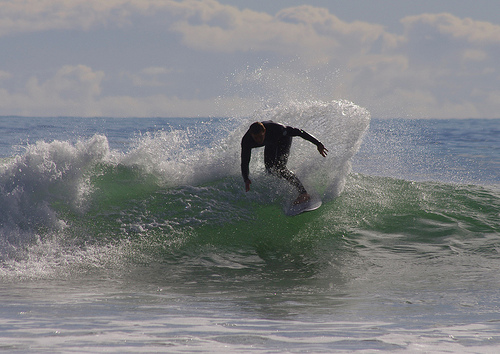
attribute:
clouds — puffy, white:
[1, 0, 498, 117]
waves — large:
[7, 128, 489, 293]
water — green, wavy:
[1, 94, 498, 351]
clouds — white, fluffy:
[17, 10, 467, 90]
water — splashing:
[88, 210, 238, 265]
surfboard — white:
[278, 187, 322, 218]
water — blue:
[311, 170, 483, 325]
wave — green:
[129, 186, 492, 236]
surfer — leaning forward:
[236, 120, 334, 210]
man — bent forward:
[241, 120, 328, 204]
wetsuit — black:
[268, 137, 309, 170]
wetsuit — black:
[237, 112, 304, 195]